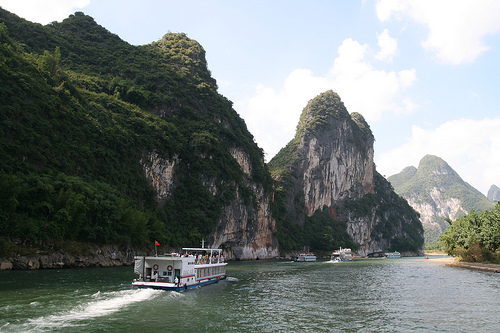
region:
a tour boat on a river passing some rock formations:
[118, 221, 255, 311]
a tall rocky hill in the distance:
[397, 143, 492, 247]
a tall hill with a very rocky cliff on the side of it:
[262, 87, 430, 270]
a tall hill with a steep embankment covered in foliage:
[7, 12, 277, 257]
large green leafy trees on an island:
[444, 214, 499, 258]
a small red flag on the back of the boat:
[147, 237, 163, 253]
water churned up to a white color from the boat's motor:
[43, 282, 161, 327]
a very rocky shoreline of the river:
[7, 233, 134, 270]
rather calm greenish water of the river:
[305, 277, 470, 332]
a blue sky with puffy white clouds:
[330, 11, 480, 98]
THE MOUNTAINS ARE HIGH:
[1, 5, 499, 257]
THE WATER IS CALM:
[5, 242, 499, 332]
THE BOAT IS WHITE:
[121, 227, 228, 297]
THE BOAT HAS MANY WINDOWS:
[183, 263, 229, 280]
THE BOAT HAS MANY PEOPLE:
[177, 251, 230, 280]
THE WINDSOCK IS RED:
[151, 235, 163, 250]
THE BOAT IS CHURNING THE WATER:
[14, 287, 171, 331]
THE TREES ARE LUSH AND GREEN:
[433, 192, 499, 262]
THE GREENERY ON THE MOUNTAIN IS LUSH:
[1, 4, 499, 259]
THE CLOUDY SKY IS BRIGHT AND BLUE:
[1, 2, 499, 212]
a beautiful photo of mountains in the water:
[8, 5, 498, 310]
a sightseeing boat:
[132, 242, 273, 312]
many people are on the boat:
[128, 232, 245, 303]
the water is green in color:
[209, 307, 379, 328]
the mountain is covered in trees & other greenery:
[3, 10, 279, 265]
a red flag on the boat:
[144, 233, 165, 260]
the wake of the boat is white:
[54, 280, 177, 320]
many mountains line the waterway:
[1, 5, 499, 264]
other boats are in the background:
[290, 241, 388, 272]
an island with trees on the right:
[417, 190, 499, 281]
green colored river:
[3, 236, 498, 331]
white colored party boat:
[126, 237, 233, 299]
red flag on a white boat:
[151, 238, 163, 258]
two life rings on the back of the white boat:
[151, 260, 176, 272]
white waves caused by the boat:
[23, 277, 171, 325]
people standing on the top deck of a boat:
[174, 247, 226, 265]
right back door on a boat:
[173, 265, 182, 284]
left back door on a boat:
[145, 264, 152, 281]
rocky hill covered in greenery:
[0, 2, 433, 269]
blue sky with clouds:
[7, 0, 499, 197]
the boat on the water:
[132, 235, 231, 287]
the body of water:
[277, 268, 424, 330]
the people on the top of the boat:
[177, 248, 220, 265]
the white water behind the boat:
[80, 282, 145, 319]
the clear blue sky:
[227, 10, 321, 54]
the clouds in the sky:
[315, 0, 497, 91]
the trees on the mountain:
[11, 80, 126, 205]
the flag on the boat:
[153, 237, 158, 256]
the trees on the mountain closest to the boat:
[28, 81, 116, 208]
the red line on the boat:
[181, 273, 193, 279]